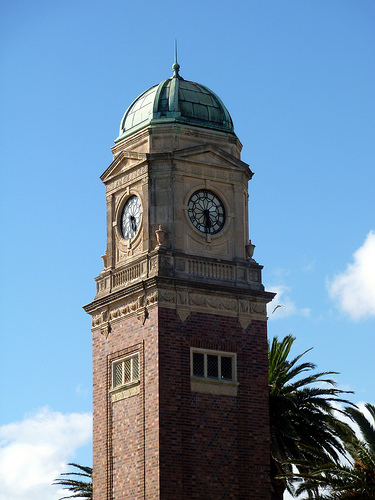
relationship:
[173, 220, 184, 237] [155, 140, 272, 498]
stone on wall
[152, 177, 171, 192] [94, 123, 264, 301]
stone in wall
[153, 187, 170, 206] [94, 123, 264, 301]
stone in wall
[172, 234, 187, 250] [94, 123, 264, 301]
stone in wall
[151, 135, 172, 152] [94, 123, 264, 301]
stone in wall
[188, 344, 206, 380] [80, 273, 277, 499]
window on building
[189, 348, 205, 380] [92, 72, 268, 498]
window on building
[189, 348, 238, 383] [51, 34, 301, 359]
window on building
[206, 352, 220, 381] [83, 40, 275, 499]
window on building